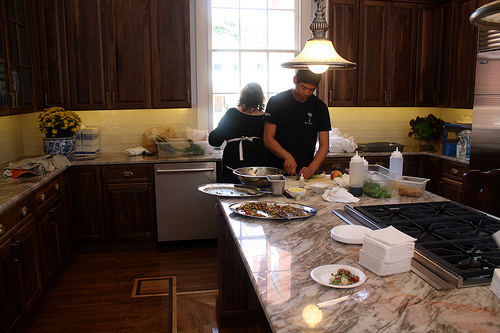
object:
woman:
[208, 82, 268, 184]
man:
[264, 70, 332, 180]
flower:
[36, 107, 83, 138]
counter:
[0, 149, 225, 214]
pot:
[43, 136, 76, 161]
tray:
[229, 200, 317, 220]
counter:
[216, 170, 500, 333]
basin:
[232, 166, 284, 187]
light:
[281, 38, 357, 74]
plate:
[310, 261, 368, 291]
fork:
[317, 288, 370, 308]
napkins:
[358, 225, 418, 276]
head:
[293, 69, 321, 100]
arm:
[263, 98, 292, 156]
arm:
[308, 114, 329, 166]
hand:
[284, 159, 297, 175]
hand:
[299, 166, 314, 179]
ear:
[293, 76, 298, 85]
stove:
[353, 201, 500, 281]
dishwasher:
[153, 162, 216, 242]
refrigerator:
[467, 27, 500, 171]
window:
[211, 0, 301, 130]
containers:
[159, 141, 214, 156]